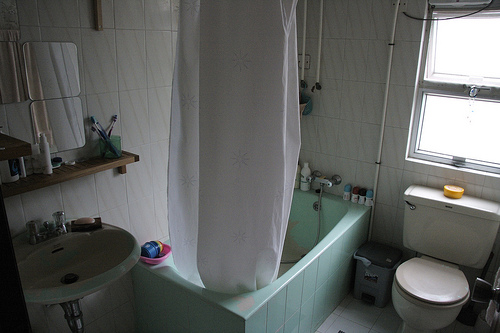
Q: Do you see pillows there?
A: No, there are no pillows.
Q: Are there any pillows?
A: No, there are no pillows.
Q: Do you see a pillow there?
A: No, there are no pillows.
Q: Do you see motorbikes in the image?
A: No, there are no motorbikes.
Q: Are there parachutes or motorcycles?
A: No, there are no motorcycles or parachutes.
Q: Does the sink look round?
A: Yes, the sink is round.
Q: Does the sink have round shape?
A: Yes, the sink is round.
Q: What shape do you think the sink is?
A: The sink is round.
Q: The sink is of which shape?
A: The sink is round.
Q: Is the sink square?
A: No, the sink is round.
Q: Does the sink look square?
A: No, the sink is round.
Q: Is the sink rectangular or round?
A: The sink is round.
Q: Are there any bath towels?
A: No, there are no bath towels.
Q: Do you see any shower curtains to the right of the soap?
A: Yes, there is a shower curtain to the right of the soap.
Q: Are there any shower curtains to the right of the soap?
A: Yes, there is a shower curtain to the right of the soap.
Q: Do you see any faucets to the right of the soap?
A: No, there is a shower curtain to the right of the soap.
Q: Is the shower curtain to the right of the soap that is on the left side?
A: Yes, the shower curtain is to the right of the soap.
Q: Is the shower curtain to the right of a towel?
A: No, the shower curtain is to the right of the soap.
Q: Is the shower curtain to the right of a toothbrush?
A: Yes, the shower curtain is to the right of a toothbrush.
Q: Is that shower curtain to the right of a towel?
A: No, the shower curtain is to the right of a toothbrush.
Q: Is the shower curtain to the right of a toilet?
A: No, the shower curtain is to the right of a toothbrush.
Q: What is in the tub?
A: The shower curtain is in the tub.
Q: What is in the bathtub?
A: The shower curtain is in the tub.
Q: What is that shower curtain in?
A: The shower curtain is in the tub.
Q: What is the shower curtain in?
A: The shower curtain is in the tub.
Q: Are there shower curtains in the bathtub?
A: Yes, there is a shower curtain in the bathtub.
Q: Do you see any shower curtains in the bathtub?
A: Yes, there is a shower curtain in the bathtub.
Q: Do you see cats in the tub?
A: No, there is a shower curtain in the tub.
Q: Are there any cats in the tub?
A: No, there is a shower curtain in the tub.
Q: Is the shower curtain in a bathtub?
A: Yes, the shower curtain is in a bathtub.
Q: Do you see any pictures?
A: No, there are no pictures.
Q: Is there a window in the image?
A: Yes, there is a window.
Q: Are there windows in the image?
A: Yes, there is a window.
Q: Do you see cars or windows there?
A: Yes, there is a window.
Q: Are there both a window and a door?
A: No, there is a window but no doors.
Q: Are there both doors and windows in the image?
A: No, there is a window but no doors.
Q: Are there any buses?
A: No, there are no buses.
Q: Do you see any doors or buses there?
A: No, there are no buses or doors.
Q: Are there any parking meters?
A: No, there are no parking meters.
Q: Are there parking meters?
A: No, there are no parking meters.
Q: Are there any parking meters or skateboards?
A: No, there are no parking meters or skateboards.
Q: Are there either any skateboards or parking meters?
A: No, there are no parking meters or skateboards.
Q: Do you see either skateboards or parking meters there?
A: No, there are no parking meters or skateboards.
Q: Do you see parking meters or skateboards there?
A: No, there are no parking meters or skateboards.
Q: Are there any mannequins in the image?
A: No, there are no mannequins.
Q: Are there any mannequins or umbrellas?
A: No, there are no mannequins or umbrellas.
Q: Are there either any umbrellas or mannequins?
A: No, there are no mannequins or umbrellas.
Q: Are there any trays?
A: No, there are no trays.